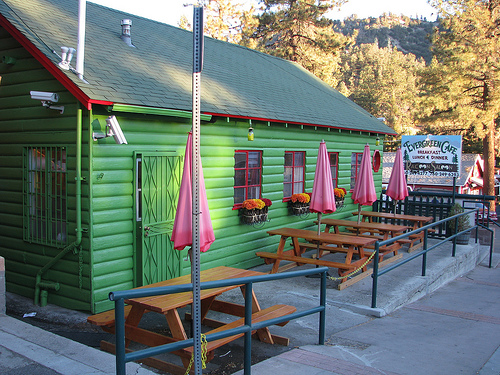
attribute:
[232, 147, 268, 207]
window — red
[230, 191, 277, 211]
flowers — orange, yellow, red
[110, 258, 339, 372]
railing — blue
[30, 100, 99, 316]
pipe — green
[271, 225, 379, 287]
picnic table — brown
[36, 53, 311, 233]
building — green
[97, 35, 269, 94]
roof — gray